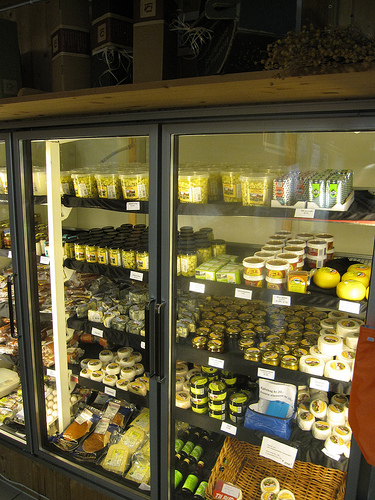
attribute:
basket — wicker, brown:
[212, 436, 348, 498]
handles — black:
[139, 296, 168, 388]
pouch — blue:
[246, 401, 291, 442]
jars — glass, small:
[193, 288, 334, 368]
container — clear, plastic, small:
[248, 227, 326, 292]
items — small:
[260, 475, 294, 500]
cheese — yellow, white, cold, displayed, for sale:
[325, 251, 372, 309]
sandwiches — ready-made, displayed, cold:
[67, 400, 119, 462]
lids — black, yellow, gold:
[189, 374, 225, 389]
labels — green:
[181, 476, 212, 497]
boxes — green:
[304, 164, 349, 211]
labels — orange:
[276, 187, 286, 197]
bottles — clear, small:
[69, 218, 222, 276]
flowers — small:
[258, 24, 374, 78]